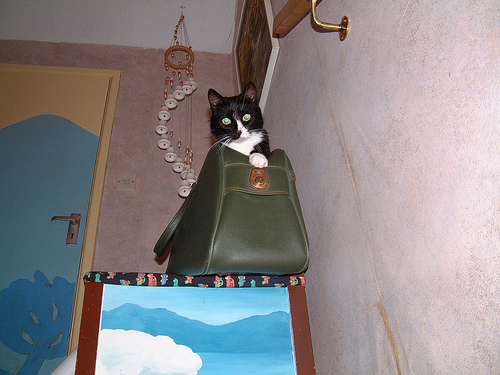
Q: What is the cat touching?
A: A purse.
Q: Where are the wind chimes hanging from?
A: Ceiling.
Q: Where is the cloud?
A: On the painting.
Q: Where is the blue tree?
A: On the door.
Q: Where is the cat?
A: On top of a bag.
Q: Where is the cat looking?
A: Down.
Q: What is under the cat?
A: Bag.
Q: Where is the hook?
A: Hanging on the wall.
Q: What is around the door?
A: Trim.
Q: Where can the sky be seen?
A: On the painting.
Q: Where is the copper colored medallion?
A: On the side of the bag.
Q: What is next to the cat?
A: A door.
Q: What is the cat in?
A: A green bag.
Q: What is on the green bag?
A: A grommet.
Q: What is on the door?
A: Silver handle.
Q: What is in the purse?
A: A cat.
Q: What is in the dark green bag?
A: A cat.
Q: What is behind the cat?
A: A wind chime.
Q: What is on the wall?
A: A framed picture.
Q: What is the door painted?
A: Blue and tan.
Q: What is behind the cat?
A: Wind chime.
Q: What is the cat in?
A: A purse.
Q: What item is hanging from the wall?
A: A decoration.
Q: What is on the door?
A: Paintings.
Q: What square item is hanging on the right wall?
A: A picture.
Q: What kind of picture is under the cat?
A: Cloud, mountain water picture.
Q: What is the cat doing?
A: Looking at the camera.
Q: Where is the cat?
A: Inside the bag.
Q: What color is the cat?
A: Black and white.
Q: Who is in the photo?
A: No one.